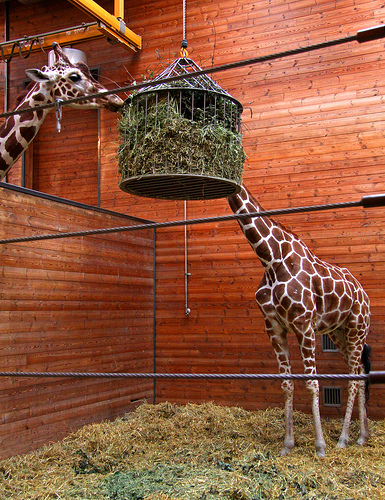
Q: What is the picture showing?
A: It is showing a pen.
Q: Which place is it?
A: It is a pen.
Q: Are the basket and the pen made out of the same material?
A: Yes, both the basket and the pen are made of metal.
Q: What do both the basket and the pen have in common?
A: The material, both the basket and the pen are metallic.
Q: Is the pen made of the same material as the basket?
A: Yes, both the pen and the basket are made of metal.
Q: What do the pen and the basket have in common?
A: The material, both the pen and the basket are metallic.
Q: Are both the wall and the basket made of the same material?
A: No, the wall is made of wood and the basket is made of metal.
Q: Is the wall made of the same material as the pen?
A: No, the wall is made of wood and the pen is made of metal.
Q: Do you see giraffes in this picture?
A: Yes, there is a giraffe.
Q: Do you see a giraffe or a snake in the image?
A: Yes, there is a giraffe.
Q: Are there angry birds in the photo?
A: No, there are no angry birds.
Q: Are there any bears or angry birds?
A: No, there are no angry birds or bears.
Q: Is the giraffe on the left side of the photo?
A: Yes, the giraffe is on the left of the image.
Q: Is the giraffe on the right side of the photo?
A: No, the giraffe is on the left of the image.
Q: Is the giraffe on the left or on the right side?
A: The giraffe is on the left of the image.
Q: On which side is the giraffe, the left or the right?
A: The giraffe is on the left of the image.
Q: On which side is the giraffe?
A: The giraffe is on the left of the image.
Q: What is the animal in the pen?
A: The animal is a giraffe.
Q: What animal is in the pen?
A: The animal is a giraffe.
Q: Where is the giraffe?
A: The giraffe is in the pen.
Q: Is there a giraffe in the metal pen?
A: Yes, there is a giraffe in the pen.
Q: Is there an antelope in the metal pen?
A: No, there is a giraffe in the pen.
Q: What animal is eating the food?
A: The giraffe is eating the food.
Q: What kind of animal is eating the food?
A: The animal is a giraffe.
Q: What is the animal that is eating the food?
A: The animal is a giraffe.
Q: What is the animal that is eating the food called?
A: The animal is a giraffe.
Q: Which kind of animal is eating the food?
A: The animal is a giraffe.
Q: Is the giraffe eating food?
A: Yes, the giraffe is eating food.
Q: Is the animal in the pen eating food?
A: Yes, the giraffe is eating food.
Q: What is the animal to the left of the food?
A: The animal is a giraffe.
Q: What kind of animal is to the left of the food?
A: The animal is a giraffe.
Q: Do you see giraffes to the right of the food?
A: No, the giraffe is to the left of the food.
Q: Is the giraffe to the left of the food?
A: Yes, the giraffe is to the left of the food.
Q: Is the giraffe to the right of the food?
A: No, the giraffe is to the left of the food.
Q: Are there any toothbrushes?
A: No, there are no toothbrushes.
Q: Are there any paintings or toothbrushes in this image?
A: No, there are no toothbrushes or paintings.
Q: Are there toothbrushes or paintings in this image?
A: No, there are no toothbrushes or paintings.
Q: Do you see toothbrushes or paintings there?
A: No, there are no toothbrushes or paintings.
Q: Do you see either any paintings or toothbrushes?
A: No, there are no toothbrushes or paintings.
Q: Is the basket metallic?
A: Yes, the basket is metallic.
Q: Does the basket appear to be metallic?
A: Yes, the basket is metallic.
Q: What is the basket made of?
A: The basket is made of metal.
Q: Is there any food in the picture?
A: Yes, there is food.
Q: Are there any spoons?
A: No, there are no spoons.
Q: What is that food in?
A: The food is in the basket.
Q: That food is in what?
A: The food is in the basket.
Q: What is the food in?
A: The food is in the basket.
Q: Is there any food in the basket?
A: Yes, there is food in the basket.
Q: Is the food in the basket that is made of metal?
A: Yes, the food is in the basket.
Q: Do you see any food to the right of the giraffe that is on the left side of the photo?
A: Yes, there is food to the right of the giraffe.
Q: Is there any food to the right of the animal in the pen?
A: Yes, there is food to the right of the giraffe.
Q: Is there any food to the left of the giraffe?
A: No, the food is to the right of the giraffe.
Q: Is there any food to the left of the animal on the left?
A: No, the food is to the right of the giraffe.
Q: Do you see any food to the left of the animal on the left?
A: No, the food is to the right of the giraffe.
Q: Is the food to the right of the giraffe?
A: Yes, the food is to the right of the giraffe.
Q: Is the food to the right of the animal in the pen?
A: Yes, the food is to the right of the giraffe.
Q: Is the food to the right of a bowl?
A: No, the food is to the right of the giraffe.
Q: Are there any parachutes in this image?
A: No, there are no parachutes.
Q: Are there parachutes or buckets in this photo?
A: No, there are no parachutes or buckets.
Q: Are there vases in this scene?
A: No, there are no vases.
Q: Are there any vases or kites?
A: No, there are no vases or kites.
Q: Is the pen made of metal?
A: Yes, the pen is made of metal.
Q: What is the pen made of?
A: The pen is made of metal.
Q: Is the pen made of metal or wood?
A: The pen is made of metal.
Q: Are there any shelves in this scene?
A: No, there are no shelves.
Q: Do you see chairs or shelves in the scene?
A: No, there are no shelves or chairs.